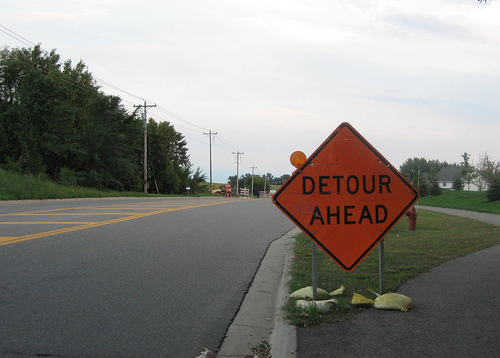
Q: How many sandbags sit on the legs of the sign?
A: Three.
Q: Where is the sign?
A: On the curb.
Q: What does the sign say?
A: Detour Ahead.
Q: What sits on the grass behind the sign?
A: A fire hydrant.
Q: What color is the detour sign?
A: Orange.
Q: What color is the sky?
A: Gray.